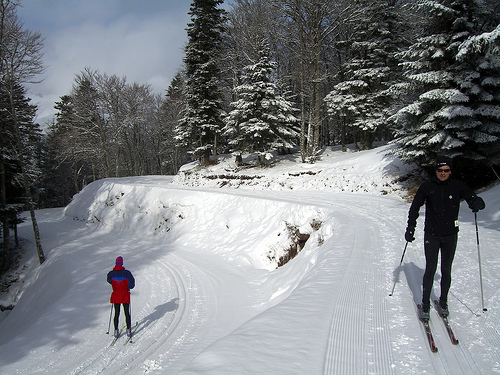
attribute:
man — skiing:
[405, 155, 486, 322]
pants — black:
[421, 231, 458, 308]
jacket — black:
[403, 176, 482, 230]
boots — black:
[420, 296, 449, 323]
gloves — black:
[403, 196, 485, 242]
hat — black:
[430, 155, 452, 173]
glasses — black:
[433, 165, 449, 175]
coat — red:
[104, 267, 135, 304]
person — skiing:
[107, 255, 136, 336]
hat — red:
[113, 253, 125, 268]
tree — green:
[216, 46, 299, 158]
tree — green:
[374, 3, 499, 175]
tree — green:
[325, 0, 403, 146]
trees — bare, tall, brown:
[1, 1, 378, 264]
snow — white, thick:
[1, 138, 498, 373]